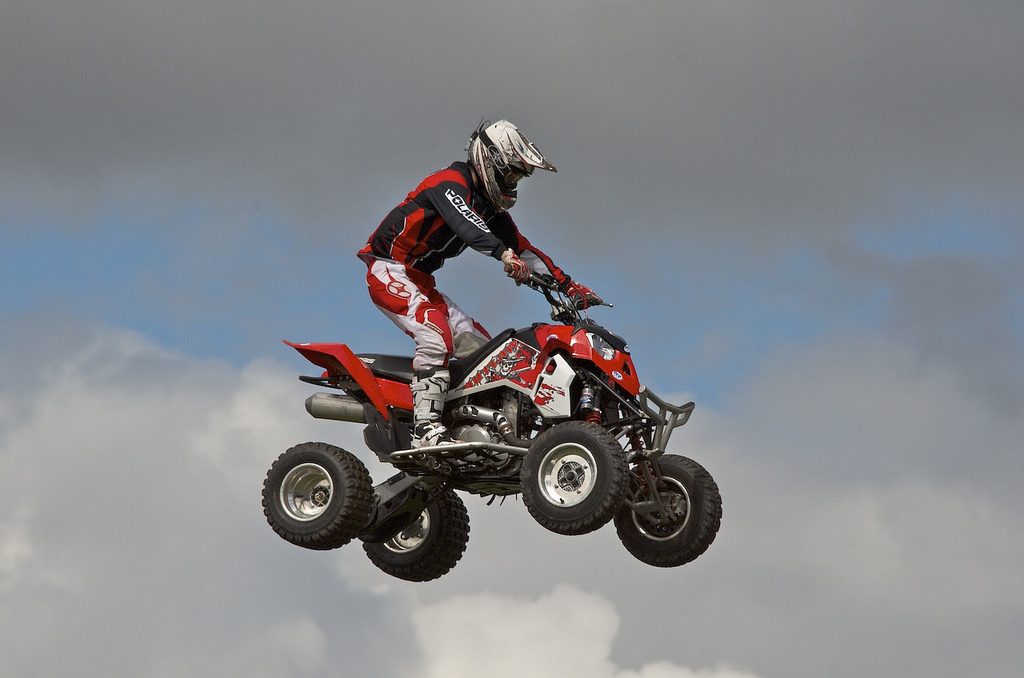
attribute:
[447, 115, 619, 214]
helmet — black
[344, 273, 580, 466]
pants — white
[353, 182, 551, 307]
jacket — black 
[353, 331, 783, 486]
four wheeler — black 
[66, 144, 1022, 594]
sky — blue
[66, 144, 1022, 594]
clouds — white, gray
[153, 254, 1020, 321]
clouds — gray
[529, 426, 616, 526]
tire — black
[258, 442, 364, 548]
tire — back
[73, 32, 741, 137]
clouds — rain clouds